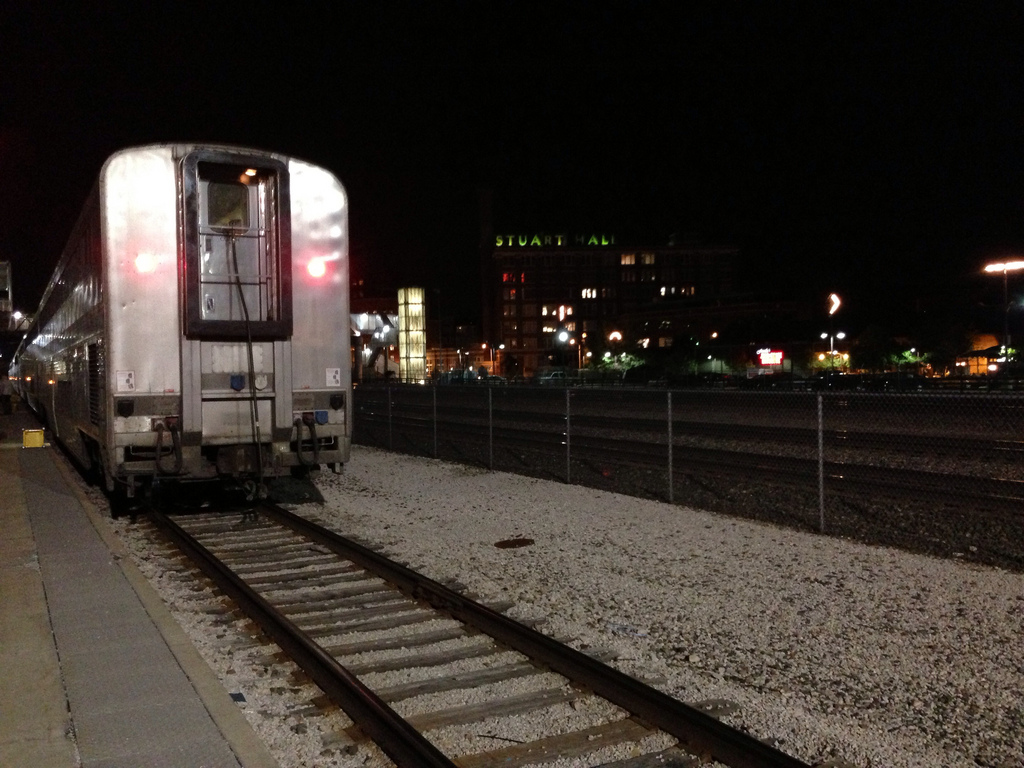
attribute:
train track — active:
[158, 509, 830, 766]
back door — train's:
[175, 143, 303, 453]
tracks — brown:
[173, 490, 815, 751]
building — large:
[487, 226, 722, 383]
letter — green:
[484, 222, 628, 249]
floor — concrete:
[3, 455, 258, 764]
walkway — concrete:
[3, 379, 280, 762]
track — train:
[164, 509, 856, 762]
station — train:
[4, 341, 998, 763]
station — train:
[0, 112, 1003, 763]